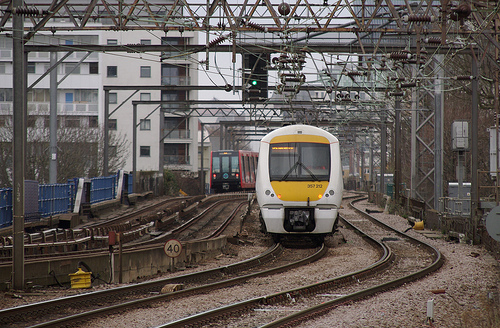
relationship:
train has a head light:
[253, 122, 344, 251] [274, 192, 283, 201]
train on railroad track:
[253, 122, 344, 251] [1, 193, 443, 323]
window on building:
[106, 66, 119, 78] [1, 8, 199, 176]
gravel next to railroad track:
[291, 293, 431, 327] [1, 193, 443, 323]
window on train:
[268, 142, 298, 179] [253, 122, 344, 251]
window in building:
[137, 65, 155, 81] [1, 8, 199, 176]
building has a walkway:
[358, 1, 495, 110] [230, 26, 421, 50]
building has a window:
[1, 8, 199, 176] [136, 143, 152, 159]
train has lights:
[253, 122, 344, 251] [264, 189, 336, 199]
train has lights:
[210, 146, 259, 190] [211, 171, 240, 181]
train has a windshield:
[253, 122, 344, 251] [267, 140, 330, 181]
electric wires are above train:
[31, 30, 393, 94] [253, 122, 344, 251]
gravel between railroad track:
[291, 293, 431, 327] [1, 193, 443, 323]